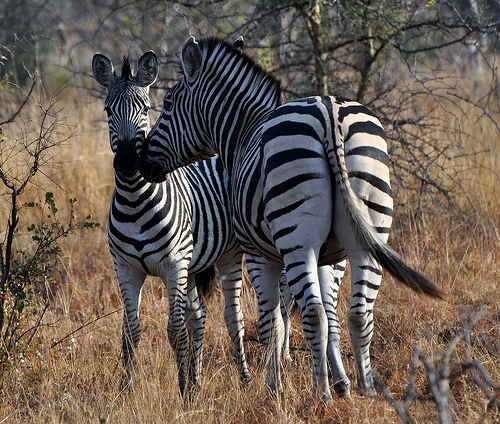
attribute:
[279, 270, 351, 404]
leg — rear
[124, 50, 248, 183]
head — turned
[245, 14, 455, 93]
trees — in background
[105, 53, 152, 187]
head — forward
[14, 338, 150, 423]
grass — dry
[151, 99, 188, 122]
eye — dark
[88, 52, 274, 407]
zebra — forward, facing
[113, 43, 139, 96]
mane — black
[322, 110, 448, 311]
tail — swishy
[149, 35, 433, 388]
zebra — facing, away